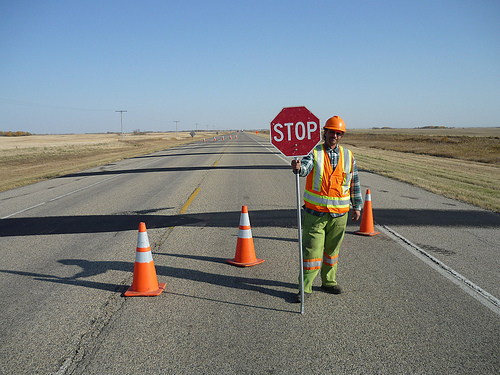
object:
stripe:
[323, 252, 338, 266]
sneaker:
[291, 291, 312, 303]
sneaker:
[318, 284, 343, 293]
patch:
[314, 145, 322, 192]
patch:
[344, 147, 350, 194]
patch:
[303, 191, 350, 205]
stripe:
[135, 250, 153, 262]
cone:
[226, 205, 265, 267]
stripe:
[238, 228, 252, 238]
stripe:
[239, 213, 250, 226]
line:
[179, 187, 202, 215]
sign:
[269, 105, 322, 157]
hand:
[291, 159, 301, 170]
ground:
[0, 126, 500, 375]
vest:
[304, 142, 353, 213]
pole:
[295, 157, 304, 313]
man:
[269, 106, 364, 314]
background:
[0, 0, 500, 146]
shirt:
[292, 142, 364, 218]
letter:
[274, 121, 317, 142]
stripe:
[137, 231, 150, 248]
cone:
[124, 221, 167, 296]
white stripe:
[365, 194, 371, 201]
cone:
[354, 189, 380, 236]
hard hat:
[323, 116, 346, 133]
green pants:
[298, 207, 347, 294]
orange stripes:
[303, 258, 322, 270]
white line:
[244, 133, 499, 315]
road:
[0, 132, 500, 375]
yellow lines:
[179, 187, 200, 213]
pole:
[121, 111, 123, 139]